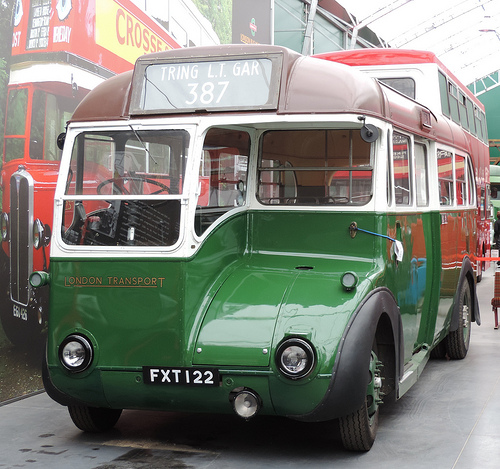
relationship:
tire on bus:
[334, 342, 382, 451] [21, 39, 491, 454]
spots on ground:
[28, 429, 168, 467] [0, 362, 494, 465]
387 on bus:
[185, 81, 230, 106] [21, 39, 491, 454]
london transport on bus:
[59, 273, 165, 290] [21, 39, 491, 454]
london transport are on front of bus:
[59, 273, 165, 290] [21, 39, 491, 454]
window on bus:
[439, 146, 468, 208] [21, 39, 491, 454]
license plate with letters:
[107, 327, 236, 412] [142, 360, 220, 391]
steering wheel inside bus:
[94, 173, 172, 239] [21, 39, 491, 454]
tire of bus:
[444, 262, 489, 362] [15, 20, 495, 395]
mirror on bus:
[356, 111, 381, 144] [21, 39, 491, 454]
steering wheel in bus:
[94, 173, 172, 227] [21, 39, 491, 454]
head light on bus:
[56, 333, 90, 372] [88, 67, 443, 463]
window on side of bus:
[371, 130, 434, 224] [17, 95, 482, 435]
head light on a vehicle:
[272, 335, 323, 380] [30, 43, 497, 450]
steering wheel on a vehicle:
[94, 173, 172, 239] [30, 43, 497, 450]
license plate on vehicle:
[142, 366, 220, 390] [30, 43, 497, 450]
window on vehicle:
[388, 130, 415, 202] [30, 43, 497, 450]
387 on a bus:
[185, 81, 230, 106] [40, 41, 485, 456]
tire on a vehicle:
[328, 412, 399, 462] [30, 43, 497, 450]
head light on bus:
[272, 335, 323, 380] [21, 39, 491, 454]